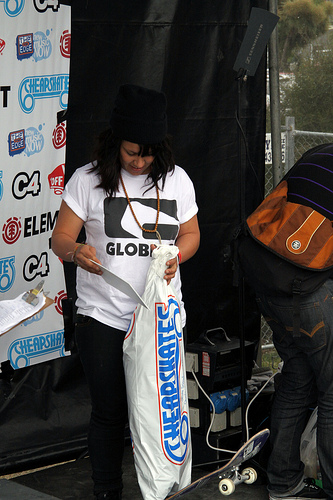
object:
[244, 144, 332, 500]
person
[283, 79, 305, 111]
ground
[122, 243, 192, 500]
bag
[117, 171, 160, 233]
necklace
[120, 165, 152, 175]
neck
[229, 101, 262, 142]
ground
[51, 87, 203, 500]
person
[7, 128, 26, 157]
emblem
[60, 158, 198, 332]
shirt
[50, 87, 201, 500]
woman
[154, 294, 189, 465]
letters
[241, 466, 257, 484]
wheels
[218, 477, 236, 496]
wheels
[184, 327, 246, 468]
wire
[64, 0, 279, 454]
equipment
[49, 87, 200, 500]
girl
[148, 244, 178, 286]
hand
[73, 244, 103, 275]
hand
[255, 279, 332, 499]
jeans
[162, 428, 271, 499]
skateboard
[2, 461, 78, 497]
ground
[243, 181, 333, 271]
bag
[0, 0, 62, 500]
side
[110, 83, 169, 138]
hat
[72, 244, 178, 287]
hands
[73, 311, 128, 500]
pants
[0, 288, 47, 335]
clipboard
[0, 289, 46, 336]
papers